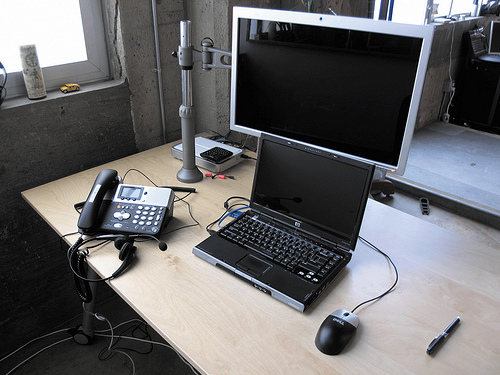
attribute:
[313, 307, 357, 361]
mouse — computer mouse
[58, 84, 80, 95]
car — matchbox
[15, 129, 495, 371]
desk — wooden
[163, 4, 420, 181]
monitor — computer monitor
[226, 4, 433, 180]
monitor — computer monitor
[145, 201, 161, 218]
button — silver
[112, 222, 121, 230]
button — silver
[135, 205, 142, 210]
button — silver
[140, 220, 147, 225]
button — silver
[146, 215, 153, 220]
button — silver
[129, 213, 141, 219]
button — silver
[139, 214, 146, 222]
button — silver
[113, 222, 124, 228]
button — silver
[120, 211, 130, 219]
button — silver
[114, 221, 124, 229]
button — silver 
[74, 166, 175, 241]
phone — landline